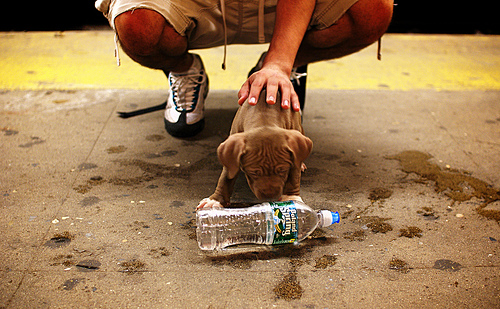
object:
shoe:
[160, 66, 206, 139]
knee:
[105, 5, 182, 65]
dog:
[198, 76, 313, 210]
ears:
[218, 131, 313, 166]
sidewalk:
[0, 25, 500, 308]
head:
[217, 125, 314, 207]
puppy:
[208, 86, 310, 203]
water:
[0, 126, 499, 308]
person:
[113, 0, 395, 136]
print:
[141, 242, 173, 262]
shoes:
[163, 53, 309, 138]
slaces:
[175, 74, 205, 88]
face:
[240, 128, 297, 203]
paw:
[194, 191, 221, 216]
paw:
[273, 186, 305, 206]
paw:
[293, 157, 309, 174]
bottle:
[190, 196, 342, 256]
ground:
[0, 30, 499, 301]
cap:
[332, 211, 339, 222]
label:
[269, 200, 297, 246]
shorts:
[90, 0, 392, 51]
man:
[90, 1, 392, 132]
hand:
[236, 66, 303, 110]